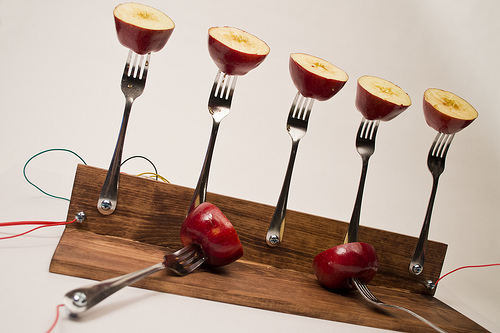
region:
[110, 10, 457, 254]
Forks with apples on them.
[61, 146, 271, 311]
Apples on the forks.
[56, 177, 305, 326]
Fork on the wood.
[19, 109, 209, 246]
Wires on the wood.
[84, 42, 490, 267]
Five forks on the wood.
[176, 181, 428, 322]
Two apples on the wood.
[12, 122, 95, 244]
Green wire on the wood.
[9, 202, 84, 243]
Red wire on the wood.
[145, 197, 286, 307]
Red apple on the fork.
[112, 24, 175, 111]
Tines on the fork.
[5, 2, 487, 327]
Metal forks screwed to a wooden board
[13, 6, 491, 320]
forks with red apples attached to them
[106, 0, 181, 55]
half of a red apple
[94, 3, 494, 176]
apple halves attached to metal forks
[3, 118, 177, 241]
red, green and yellow wires attached to a wooden board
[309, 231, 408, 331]
half of a red apple attached to fork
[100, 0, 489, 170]
five apple halves attached to forks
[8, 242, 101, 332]
red wire screwed to handle of metal fork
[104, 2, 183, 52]
bottom half of a red apple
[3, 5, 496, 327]
wooden contraption made with forks, screws, wire and apples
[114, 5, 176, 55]
Apple stuck on fork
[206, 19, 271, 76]
Apple stuck on fork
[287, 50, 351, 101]
Apple stuck on fork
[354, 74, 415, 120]
Apple stuck on fork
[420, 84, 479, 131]
Apple stuck on fork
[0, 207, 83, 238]
Red cord attached to screw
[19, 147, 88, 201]
Teal cord by red cord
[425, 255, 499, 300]
Red cord attached to screw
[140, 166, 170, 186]
Yellow cord by teal cord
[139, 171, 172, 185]
Yellow cord behind wood piece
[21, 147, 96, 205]
Thin teal cord behind wood piece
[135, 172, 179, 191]
Thin yellow cord behind wood piece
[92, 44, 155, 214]
Silver fork holding apple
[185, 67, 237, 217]
Silver fork holding apple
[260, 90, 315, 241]
Silver fork holding apple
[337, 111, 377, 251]
Silver fork holding apple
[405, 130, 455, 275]
Silver fork holding apple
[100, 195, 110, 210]
Screw in fork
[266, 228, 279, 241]
Screw in fork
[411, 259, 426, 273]
Screw in fork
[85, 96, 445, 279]
five forks attached to a board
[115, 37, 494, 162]
five forks attached to a board with apples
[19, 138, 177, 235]
wires attached to board and forks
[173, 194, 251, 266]
red apple cut in half and attached to fork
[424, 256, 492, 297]
red wire attached to a screw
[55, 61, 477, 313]
seven forks with half an apple attached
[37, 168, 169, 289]
brown wooden board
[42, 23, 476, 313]
science experiment with apples and forks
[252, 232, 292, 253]
fork attached to board with screw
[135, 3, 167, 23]
brown center of apple